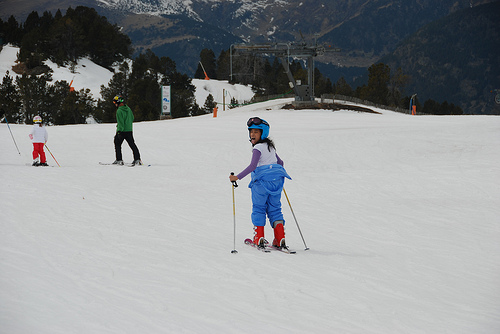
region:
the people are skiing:
[15, 83, 333, 258]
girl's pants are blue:
[244, 158, 296, 238]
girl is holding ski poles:
[201, 166, 319, 256]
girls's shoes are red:
[234, 209, 301, 255]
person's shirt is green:
[106, 101, 148, 146]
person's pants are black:
[103, 123, 157, 167]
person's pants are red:
[23, 131, 50, 168]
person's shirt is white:
[25, 123, 57, 150]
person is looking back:
[220, 106, 320, 268]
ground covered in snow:
[3, 40, 498, 331]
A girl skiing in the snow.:
[226, 115, 312, 263]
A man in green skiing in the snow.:
[93, 95, 163, 169]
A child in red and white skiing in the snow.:
[21, 110, 63, 177]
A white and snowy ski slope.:
[1, 92, 497, 331]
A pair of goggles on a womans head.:
[246, 118, 271, 145]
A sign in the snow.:
[156, 80, 178, 125]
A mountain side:
[1, 0, 496, 115]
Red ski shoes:
[241, 221, 294, 253]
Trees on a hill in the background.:
[0, 8, 466, 122]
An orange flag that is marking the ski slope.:
[38, 75, 80, 150]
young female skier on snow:
[227, 113, 316, 255]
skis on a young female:
[240, 234, 297, 261]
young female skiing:
[230, 113, 315, 254]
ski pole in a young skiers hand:
[227, 170, 242, 256]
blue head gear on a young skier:
[247, 120, 269, 141]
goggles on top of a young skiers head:
[245, 115, 270, 128]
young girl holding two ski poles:
[228, 114, 310, 255]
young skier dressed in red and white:
[25, 113, 51, 165]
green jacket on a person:
[115, 104, 137, 132]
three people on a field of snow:
[23, 91, 311, 256]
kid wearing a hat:
[226, 109, 320, 257]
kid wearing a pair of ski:
[217, 85, 328, 257]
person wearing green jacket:
[98, 86, 159, 171]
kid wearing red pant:
[16, 105, 63, 169]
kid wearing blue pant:
[210, 103, 332, 261]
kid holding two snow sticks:
[204, 96, 326, 257]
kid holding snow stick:
[18, 96, 74, 176]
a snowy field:
[46, 238, 191, 327]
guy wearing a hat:
[95, 95, 160, 172]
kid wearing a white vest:
[207, 118, 331, 258]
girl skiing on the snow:
[218, 104, 320, 264]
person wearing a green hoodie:
[107, 90, 152, 175]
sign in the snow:
[156, 76, 176, 118]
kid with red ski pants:
[18, 109, 62, 175]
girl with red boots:
[216, 111, 313, 264]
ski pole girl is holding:
[224, 166, 242, 261]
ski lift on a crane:
[224, 40, 323, 106]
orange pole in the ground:
[208, 102, 221, 119]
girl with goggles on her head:
[220, 110, 325, 261]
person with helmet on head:
[102, 89, 146, 169]